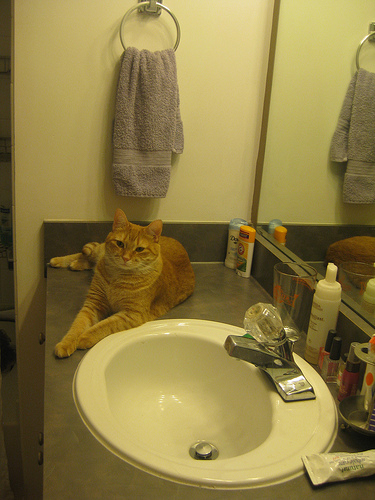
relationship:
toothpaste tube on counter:
[294, 443, 374, 482] [42, 219, 374, 496]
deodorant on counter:
[222, 217, 252, 268] [42, 219, 374, 496]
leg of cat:
[52, 258, 86, 267] [50, 207, 194, 354]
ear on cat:
[146, 214, 165, 248] [50, 207, 194, 354]